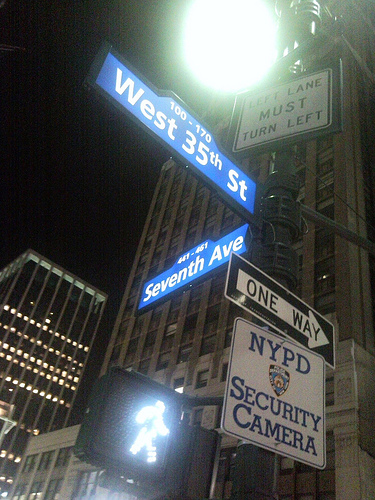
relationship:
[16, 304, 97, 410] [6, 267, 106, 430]
lights on building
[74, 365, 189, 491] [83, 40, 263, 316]
sign on street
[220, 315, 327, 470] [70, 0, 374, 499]
sign on street pole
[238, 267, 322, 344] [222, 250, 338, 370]
one way on one-way sign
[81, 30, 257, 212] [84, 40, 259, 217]
west on sign